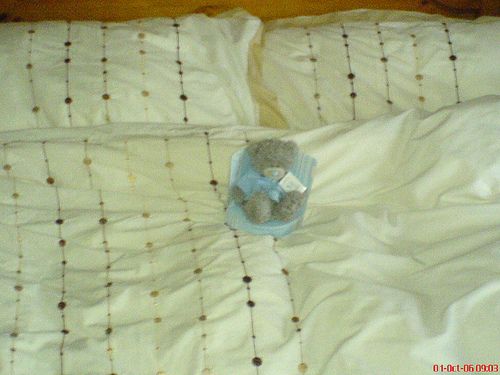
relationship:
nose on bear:
[272, 171, 279, 176] [230, 139, 307, 228]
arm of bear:
[229, 172, 259, 207] [230, 139, 307, 228]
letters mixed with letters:
[445, 358, 462, 373] [433, 364, 500, 375]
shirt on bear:
[234, 170, 286, 203] [230, 139, 307, 228]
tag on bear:
[274, 170, 308, 198] [227, 136, 300, 228]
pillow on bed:
[88, 10, 269, 160] [13, 20, 483, 371]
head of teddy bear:
[245, 132, 296, 183] [224, 132, 310, 224]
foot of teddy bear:
[273, 190, 303, 222] [230, 136, 306, 223]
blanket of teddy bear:
[229, 146, 316, 235] [234, 138, 301, 220]